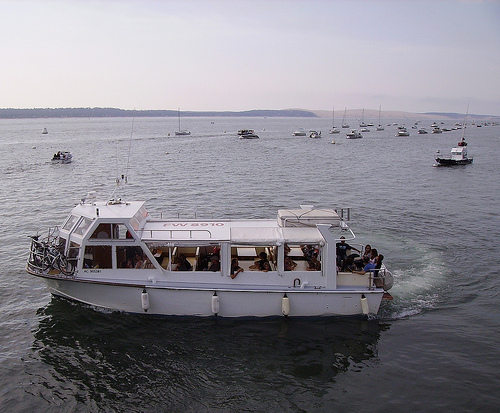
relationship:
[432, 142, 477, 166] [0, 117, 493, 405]
boat floating in water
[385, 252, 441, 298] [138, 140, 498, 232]
bubbles floating in water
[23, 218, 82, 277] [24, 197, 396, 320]
bikes hanging on boat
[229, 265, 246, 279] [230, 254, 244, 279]
arm part of person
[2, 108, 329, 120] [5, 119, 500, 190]
land next to water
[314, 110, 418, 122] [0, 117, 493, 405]
hill next to water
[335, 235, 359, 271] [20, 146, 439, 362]
people sitting on boat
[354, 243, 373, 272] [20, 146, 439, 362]
person sitting on boat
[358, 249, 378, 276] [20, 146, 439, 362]
person sitting on boat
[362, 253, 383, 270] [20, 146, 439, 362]
person sitting on boat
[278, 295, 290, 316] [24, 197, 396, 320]
buoy on boat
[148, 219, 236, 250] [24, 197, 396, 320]
railing on boat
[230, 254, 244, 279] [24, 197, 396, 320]
person sitting in boat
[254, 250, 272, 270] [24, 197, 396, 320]
person sitting in boat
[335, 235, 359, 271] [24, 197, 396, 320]
people sitting in boat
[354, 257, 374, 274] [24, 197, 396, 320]
person sitting in boat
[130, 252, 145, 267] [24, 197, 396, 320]
person sitting in boat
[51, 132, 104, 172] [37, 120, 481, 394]
bouy in water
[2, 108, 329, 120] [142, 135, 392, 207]
land by water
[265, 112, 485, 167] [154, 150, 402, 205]
boats in water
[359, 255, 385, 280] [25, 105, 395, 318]
person on boat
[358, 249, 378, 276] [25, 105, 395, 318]
person on boat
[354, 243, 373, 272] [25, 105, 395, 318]
person on boat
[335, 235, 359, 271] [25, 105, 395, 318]
people on boat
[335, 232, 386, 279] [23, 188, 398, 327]
people on boat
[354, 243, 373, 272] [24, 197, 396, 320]
person on boat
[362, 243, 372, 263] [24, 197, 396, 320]
person on boat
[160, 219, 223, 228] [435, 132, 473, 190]
number on boat